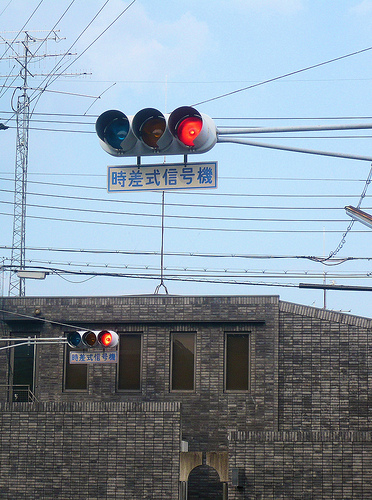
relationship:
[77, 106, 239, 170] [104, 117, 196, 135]
traffic light have colors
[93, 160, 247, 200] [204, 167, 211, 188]
sign of street name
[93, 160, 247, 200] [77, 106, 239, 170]
sign under traffic light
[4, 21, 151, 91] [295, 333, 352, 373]
wires above building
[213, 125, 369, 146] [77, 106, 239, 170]
pole holding traffic light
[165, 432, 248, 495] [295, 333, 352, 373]
archway in building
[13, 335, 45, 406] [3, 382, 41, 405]
door behind railing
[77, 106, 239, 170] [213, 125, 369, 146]
traffic light on pole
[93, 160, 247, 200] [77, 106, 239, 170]
sign on traffic light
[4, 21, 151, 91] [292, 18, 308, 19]
wires against sky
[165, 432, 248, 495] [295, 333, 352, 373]
archway on building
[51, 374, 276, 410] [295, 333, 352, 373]
windows of building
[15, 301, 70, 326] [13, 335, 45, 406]
light over door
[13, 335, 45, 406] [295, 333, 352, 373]
door of building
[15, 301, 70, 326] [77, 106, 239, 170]
light on traffic light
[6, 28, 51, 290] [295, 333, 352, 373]
antenna on building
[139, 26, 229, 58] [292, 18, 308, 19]
clouds in sky